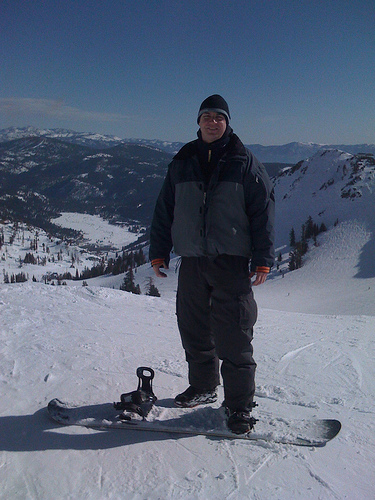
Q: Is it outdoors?
A: Yes, it is outdoors.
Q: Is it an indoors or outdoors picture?
A: It is outdoors.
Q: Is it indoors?
A: No, it is outdoors.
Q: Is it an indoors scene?
A: No, it is outdoors.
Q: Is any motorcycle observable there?
A: No, there are no motorcycles.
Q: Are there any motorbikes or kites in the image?
A: No, there are no motorbikes or kites.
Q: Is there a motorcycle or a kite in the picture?
A: No, there are no motorcycles or kites.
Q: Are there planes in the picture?
A: No, there are no planes.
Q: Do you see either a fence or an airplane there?
A: No, there are no airplanes or fences.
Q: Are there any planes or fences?
A: No, there are no planes or fences.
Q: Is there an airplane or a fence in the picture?
A: No, there are no airplanes or fences.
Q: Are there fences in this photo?
A: No, there are no fences.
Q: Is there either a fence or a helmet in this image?
A: No, there are no fences or helmets.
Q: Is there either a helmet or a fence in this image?
A: No, there are no fences or helmets.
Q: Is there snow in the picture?
A: Yes, there is snow.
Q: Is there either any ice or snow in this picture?
A: Yes, there is snow.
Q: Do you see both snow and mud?
A: No, there is snow but no mud.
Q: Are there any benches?
A: No, there are no benches.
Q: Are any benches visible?
A: No, there are no benches.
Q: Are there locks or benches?
A: No, there are no benches or locks.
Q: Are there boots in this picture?
A: Yes, there are boots.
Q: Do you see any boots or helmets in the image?
A: Yes, there are boots.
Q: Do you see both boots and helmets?
A: No, there are boots but no helmets.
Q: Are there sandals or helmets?
A: No, there are no helmets or sandals.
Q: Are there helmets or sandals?
A: No, there are no helmets or sandals.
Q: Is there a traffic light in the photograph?
A: No, there are no traffic lights.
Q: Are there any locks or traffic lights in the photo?
A: No, there are no traffic lights or locks.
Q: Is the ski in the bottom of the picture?
A: Yes, the ski is in the bottom of the image.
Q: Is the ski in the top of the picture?
A: No, the ski is in the bottom of the image.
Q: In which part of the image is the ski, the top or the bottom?
A: The ski is in the bottom of the image.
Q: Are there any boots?
A: Yes, there are boots.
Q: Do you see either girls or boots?
A: Yes, there are boots.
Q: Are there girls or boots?
A: Yes, there are boots.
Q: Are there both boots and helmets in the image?
A: No, there are boots but no helmets.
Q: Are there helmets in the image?
A: No, there are no helmets.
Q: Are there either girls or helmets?
A: No, there are no helmets or girls.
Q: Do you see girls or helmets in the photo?
A: No, there are no helmets or girls.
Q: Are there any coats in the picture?
A: Yes, there is a coat.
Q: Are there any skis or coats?
A: Yes, there is a coat.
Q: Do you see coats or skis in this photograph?
A: Yes, there is a coat.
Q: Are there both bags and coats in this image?
A: No, there is a coat but no bags.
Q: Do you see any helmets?
A: No, there are no helmets.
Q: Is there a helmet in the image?
A: No, there are no helmets.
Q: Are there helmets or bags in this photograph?
A: No, there are no helmets or bags.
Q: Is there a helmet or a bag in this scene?
A: No, there are no helmets or bags.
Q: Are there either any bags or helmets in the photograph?
A: No, there are no helmets or bags.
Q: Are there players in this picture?
A: No, there are no players.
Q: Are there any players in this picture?
A: No, there are no players.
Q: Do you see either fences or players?
A: No, there are no players or fences.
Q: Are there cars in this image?
A: No, there are no cars.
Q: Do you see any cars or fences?
A: No, there are no cars or fences.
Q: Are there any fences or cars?
A: No, there are no cars or fences.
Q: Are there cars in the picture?
A: No, there are no cars.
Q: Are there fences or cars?
A: No, there are no cars or fences.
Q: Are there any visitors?
A: No, there are no visitors.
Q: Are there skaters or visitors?
A: No, there are no visitors or skaters.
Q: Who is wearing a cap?
A: The guy is wearing a cap.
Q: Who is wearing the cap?
A: The guy is wearing a cap.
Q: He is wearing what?
A: The guy is wearing a cap.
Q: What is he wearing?
A: The guy is wearing a cap.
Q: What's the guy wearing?
A: The guy is wearing a cap.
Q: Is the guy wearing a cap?
A: Yes, the guy is wearing a cap.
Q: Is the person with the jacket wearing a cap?
A: Yes, the guy is wearing a cap.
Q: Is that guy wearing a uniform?
A: No, the guy is wearing a cap.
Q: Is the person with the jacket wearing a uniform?
A: No, the guy is wearing a cap.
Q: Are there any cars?
A: No, there are no cars.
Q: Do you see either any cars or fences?
A: No, there are no cars or fences.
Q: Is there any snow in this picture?
A: Yes, there is snow.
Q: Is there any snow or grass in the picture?
A: Yes, there is snow.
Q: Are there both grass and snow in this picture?
A: No, there is snow but no grass.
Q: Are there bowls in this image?
A: No, there are no bowls.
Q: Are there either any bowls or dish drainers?
A: No, there are no bowls or dish drainers.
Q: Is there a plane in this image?
A: No, there are no airplanes.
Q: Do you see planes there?
A: No, there are no planes.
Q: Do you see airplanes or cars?
A: No, there are no airplanes or cars.